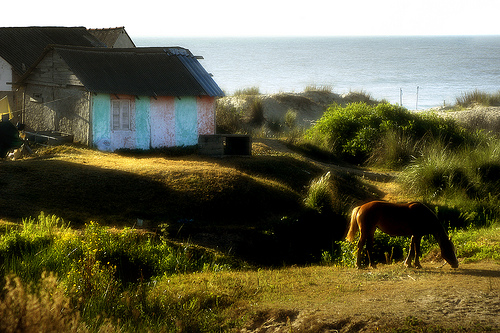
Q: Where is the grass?
A: On the ground.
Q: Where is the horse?
A: In the grass.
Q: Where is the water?
A: Past the beach.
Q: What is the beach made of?
A: Sand.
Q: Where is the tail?
A: On the horse.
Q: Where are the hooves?
A: On the horse.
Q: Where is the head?
A: On the horse.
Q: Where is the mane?
A: On the horse.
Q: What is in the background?
A: A small house.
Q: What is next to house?
A: Body of water.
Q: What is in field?
A: A horse.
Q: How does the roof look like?
A: Black and sloped.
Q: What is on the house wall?
A: Blue and pink plastic.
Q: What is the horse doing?
A: Eating.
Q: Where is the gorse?
A: On grassy land.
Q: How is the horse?
A: Standing on his feet.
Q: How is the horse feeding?
A: Eating from grassland.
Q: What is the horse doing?
A: Eating grass.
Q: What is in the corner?
A: A barn.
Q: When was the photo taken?
A: During the day.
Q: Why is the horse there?
A: It lives there.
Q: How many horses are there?
A: One.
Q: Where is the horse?
A: In the yard.